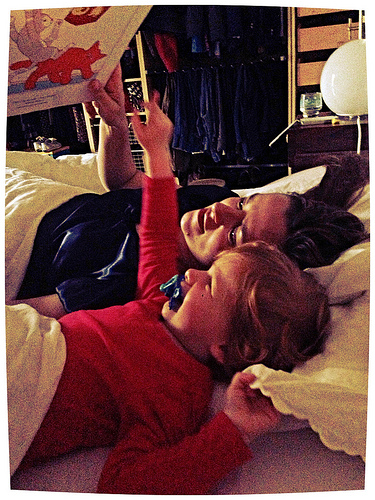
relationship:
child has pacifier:
[7, 87, 331, 492] [161, 274, 182, 310]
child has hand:
[7, 87, 331, 492] [129, 92, 174, 150]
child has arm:
[7, 87, 331, 492] [136, 148, 180, 301]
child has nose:
[7, 87, 331, 492] [184, 266, 209, 284]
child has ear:
[7, 87, 331, 492] [209, 341, 225, 362]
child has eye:
[7, 87, 331, 492] [205, 275, 215, 298]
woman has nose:
[8, 61, 370, 320] [209, 202, 241, 225]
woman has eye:
[8, 61, 370, 320] [229, 222, 239, 246]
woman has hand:
[8, 61, 370, 320] [84, 61, 127, 127]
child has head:
[7, 87, 331, 492] [160, 241, 333, 368]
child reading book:
[7, 87, 331, 492] [4, 6, 157, 119]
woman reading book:
[8, 61, 370, 320] [4, 6, 157, 119]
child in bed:
[7, 87, 331, 492] [9, 164, 367, 493]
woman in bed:
[8, 61, 370, 320] [9, 164, 367, 493]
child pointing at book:
[7, 87, 331, 492] [4, 6, 157, 119]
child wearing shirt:
[7, 87, 331, 492] [20, 173, 253, 494]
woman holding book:
[8, 61, 370, 320] [4, 6, 157, 119]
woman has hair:
[8, 61, 370, 320] [279, 147, 374, 271]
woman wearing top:
[8, 61, 370, 320] [12, 182, 244, 316]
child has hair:
[7, 87, 331, 492] [205, 238, 329, 384]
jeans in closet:
[197, 65, 215, 153] [137, 6, 285, 191]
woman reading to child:
[8, 61, 370, 320] [7, 87, 331, 492]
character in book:
[9, 40, 109, 88] [4, 6, 157, 119]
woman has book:
[8, 61, 370, 320] [4, 6, 157, 119]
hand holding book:
[84, 61, 127, 127] [4, 6, 157, 119]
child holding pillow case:
[7, 87, 331, 492] [240, 290, 374, 466]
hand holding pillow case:
[227, 368, 283, 437] [240, 290, 374, 466]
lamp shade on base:
[319, 36, 368, 119] [354, 114, 362, 156]